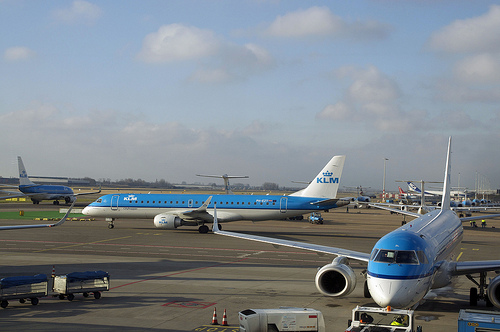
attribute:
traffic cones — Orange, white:
[211, 302, 229, 326]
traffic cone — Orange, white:
[207, 304, 217, 324]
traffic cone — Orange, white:
[220, 306, 228, 324]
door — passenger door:
[277, 194, 287, 211]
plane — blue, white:
[76, 140, 361, 240]